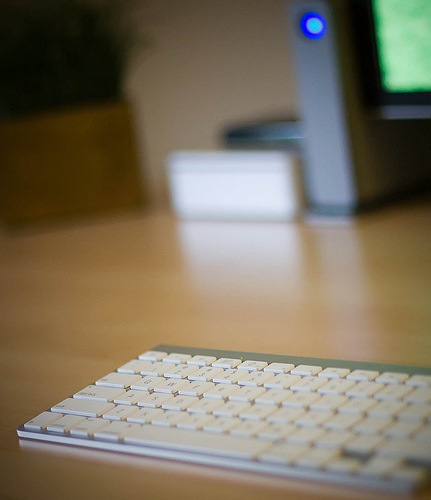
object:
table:
[0, 192, 430, 500]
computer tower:
[285, 1, 418, 216]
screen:
[368, 0, 430, 93]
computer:
[346, 0, 430, 119]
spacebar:
[124, 424, 266, 471]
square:
[165, 147, 305, 226]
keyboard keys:
[256, 420, 291, 445]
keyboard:
[15, 342, 430, 498]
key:
[134, 348, 167, 363]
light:
[295, 9, 325, 43]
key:
[257, 383, 289, 405]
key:
[242, 402, 281, 420]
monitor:
[359, 0, 430, 106]